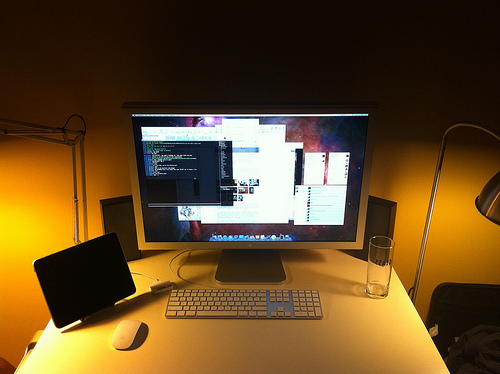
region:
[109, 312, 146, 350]
A mouse on the desk.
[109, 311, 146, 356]
A white computer mouse.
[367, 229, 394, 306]
A clear glass.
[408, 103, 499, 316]
A silver floor lamp.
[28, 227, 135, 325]
A clock turned off.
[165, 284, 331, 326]
A computer keyboard.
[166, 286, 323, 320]
The keys are white.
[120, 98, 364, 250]
The computer moniter.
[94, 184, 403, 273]
Speakers behind the moniter.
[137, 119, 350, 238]
Tasks open on the computer moniter.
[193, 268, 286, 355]
the table is white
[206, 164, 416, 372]
the table is white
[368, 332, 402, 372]
the table is white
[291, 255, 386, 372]
the table is white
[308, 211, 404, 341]
the table is white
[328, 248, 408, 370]
the table is white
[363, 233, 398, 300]
a empty glass on a table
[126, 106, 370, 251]
a computer monitor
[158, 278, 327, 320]
a computer keyboard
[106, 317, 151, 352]
a computer mouse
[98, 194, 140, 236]
a computer speaker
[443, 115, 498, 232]
a lamp beside a table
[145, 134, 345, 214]
the screen of a computer monitor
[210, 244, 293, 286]
the base of a computer monitor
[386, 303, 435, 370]
a table top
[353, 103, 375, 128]
the corner of a computer monitor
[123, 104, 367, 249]
apple computer monitor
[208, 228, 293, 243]
apple computer dock at bottom of screen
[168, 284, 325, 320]
white and silver apple keyboard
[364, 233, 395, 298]
clear, empty glass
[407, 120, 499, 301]
tall silver lamp is on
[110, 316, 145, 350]
white, wireless apple mouse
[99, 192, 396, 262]
set of speakers behind computer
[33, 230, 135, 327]
black tablet next to computer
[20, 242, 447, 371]
clean white desk for computer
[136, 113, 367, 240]
computer screen is lit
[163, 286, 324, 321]
Keyboard in front of monitor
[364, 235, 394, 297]
Glass next to monitor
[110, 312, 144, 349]
Mouse is white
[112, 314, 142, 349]
Mouse next to keyboard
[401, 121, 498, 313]
Lamp by monitor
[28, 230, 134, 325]
iPad mini next to mouse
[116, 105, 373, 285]
Monitor on large white table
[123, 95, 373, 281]
Big monitor is on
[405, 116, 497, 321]
Lamp is stainless steel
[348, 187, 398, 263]
Speaker behind monitor